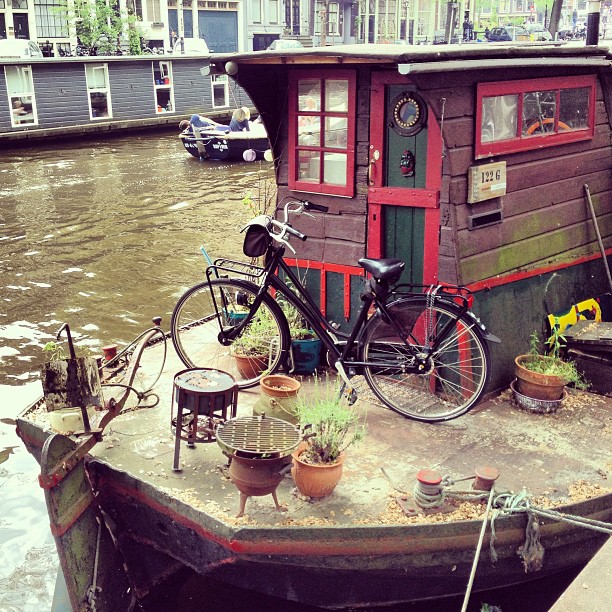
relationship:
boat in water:
[175, 105, 272, 160] [23, 162, 207, 307]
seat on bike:
[356, 248, 398, 281] [178, 259, 488, 402]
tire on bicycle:
[170, 277, 286, 380] [171, 196, 504, 424]